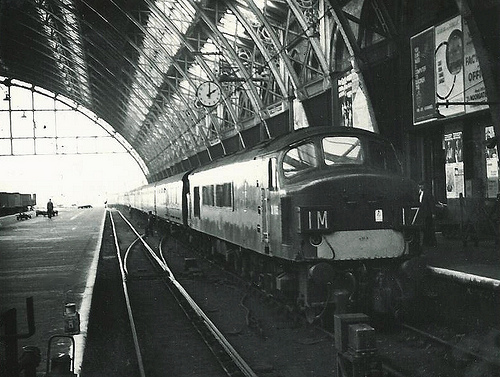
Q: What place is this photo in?
A: It is at the station.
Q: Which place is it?
A: It is a station.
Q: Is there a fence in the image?
A: No, there are no fences.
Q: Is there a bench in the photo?
A: No, there are no benches.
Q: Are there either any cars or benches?
A: No, there are no benches or cars.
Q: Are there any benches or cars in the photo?
A: No, there are no benches or cars.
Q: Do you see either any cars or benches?
A: No, there are no benches or cars.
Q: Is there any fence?
A: No, there are no fences.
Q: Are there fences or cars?
A: No, there are no fences or cars.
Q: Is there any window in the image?
A: Yes, there is a window.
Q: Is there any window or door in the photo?
A: Yes, there is a window.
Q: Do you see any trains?
A: Yes, there is a train.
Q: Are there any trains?
A: Yes, there is a train.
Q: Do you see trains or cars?
A: Yes, there is a train.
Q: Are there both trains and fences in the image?
A: No, there is a train but no fences.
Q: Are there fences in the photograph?
A: No, there are no fences.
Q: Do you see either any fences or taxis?
A: No, there are no fences or taxis.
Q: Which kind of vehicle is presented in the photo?
A: The vehicle is a train.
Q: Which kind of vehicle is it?
A: The vehicle is a train.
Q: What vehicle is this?
A: That is a train.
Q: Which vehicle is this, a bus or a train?
A: That is a train.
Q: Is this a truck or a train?
A: This is a train.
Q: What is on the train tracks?
A: The train is on the train tracks.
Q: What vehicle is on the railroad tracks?
A: The vehicle is a train.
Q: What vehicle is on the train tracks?
A: The vehicle is a train.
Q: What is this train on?
A: The train is on the train tracks.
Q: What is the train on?
A: The train is on the train tracks.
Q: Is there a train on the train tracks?
A: Yes, there is a train on the train tracks.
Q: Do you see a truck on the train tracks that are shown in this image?
A: No, there is a train on the train tracks.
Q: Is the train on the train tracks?
A: Yes, the train is on the train tracks.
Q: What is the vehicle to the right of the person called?
A: The vehicle is a train.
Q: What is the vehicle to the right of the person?
A: The vehicle is a train.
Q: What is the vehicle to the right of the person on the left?
A: The vehicle is a train.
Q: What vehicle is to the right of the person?
A: The vehicle is a train.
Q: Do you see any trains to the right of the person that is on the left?
A: Yes, there is a train to the right of the person.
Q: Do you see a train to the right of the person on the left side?
A: Yes, there is a train to the right of the person.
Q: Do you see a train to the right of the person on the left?
A: Yes, there is a train to the right of the person.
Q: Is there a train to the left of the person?
A: No, the train is to the right of the person.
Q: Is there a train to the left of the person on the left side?
A: No, the train is to the right of the person.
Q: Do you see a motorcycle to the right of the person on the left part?
A: No, there is a train to the right of the person.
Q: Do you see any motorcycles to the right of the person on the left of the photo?
A: No, there is a train to the right of the person.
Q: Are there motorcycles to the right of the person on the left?
A: No, there is a train to the right of the person.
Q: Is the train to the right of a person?
A: Yes, the train is to the right of a person.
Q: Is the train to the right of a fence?
A: No, the train is to the right of a person.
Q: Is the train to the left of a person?
A: No, the train is to the right of a person.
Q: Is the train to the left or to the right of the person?
A: The train is to the right of the person.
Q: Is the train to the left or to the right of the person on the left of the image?
A: The train is to the right of the person.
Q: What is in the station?
A: The train is in the station.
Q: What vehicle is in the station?
A: The vehicle is a train.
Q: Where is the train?
A: The train is in the station.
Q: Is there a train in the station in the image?
A: Yes, there is a train in the station.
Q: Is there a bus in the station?
A: No, there is a train in the station.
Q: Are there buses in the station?
A: No, there is a train in the station.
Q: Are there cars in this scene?
A: No, there are no cars.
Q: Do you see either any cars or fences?
A: No, there are no cars or fences.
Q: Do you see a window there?
A: Yes, there is a window.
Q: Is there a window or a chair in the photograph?
A: Yes, there is a window.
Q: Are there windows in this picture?
A: Yes, there is a window.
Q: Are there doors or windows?
A: Yes, there is a window.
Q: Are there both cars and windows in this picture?
A: No, there is a window but no cars.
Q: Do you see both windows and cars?
A: No, there is a window but no cars.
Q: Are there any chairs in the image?
A: No, there are no chairs.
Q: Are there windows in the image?
A: Yes, there is a window.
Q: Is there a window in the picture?
A: Yes, there is a window.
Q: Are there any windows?
A: Yes, there is a window.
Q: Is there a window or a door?
A: Yes, there is a window.